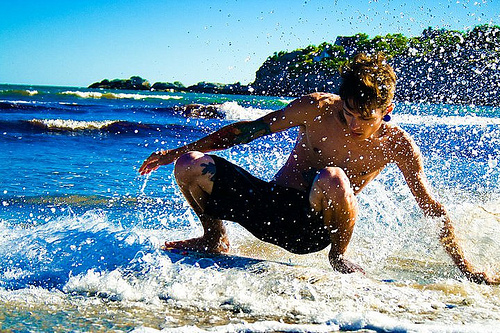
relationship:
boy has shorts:
[132, 56, 498, 291] [203, 147, 335, 262]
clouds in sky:
[233, 59, 264, 69] [2, 2, 496, 84]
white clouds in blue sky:
[204, 28, 261, 70] [0, 0, 497, 84]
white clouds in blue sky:
[166, 57, 255, 80] [0, 0, 497, 84]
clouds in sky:
[39, 25, 260, 85] [2, 2, 496, 84]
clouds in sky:
[164, 31, 211, 63] [19, 5, 250, 74]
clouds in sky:
[109, 27, 249, 82] [17, 3, 495, 110]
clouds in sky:
[72, 0, 256, 55] [74, 21, 246, 65]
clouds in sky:
[203, 39, 249, 52] [122, 20, 217, 75]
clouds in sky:
[160, 12, 260, 72] [79, 30, 107, 48]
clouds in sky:
[37, 32, 77, 58] [17, 3, 495, 110]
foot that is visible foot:
[328, 248, 365, 288] [328, 248, 365, 288]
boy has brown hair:
[132, 56, 498, 291] [336, 48, 403, 110]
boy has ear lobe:
[132, 56, 498, 291] [384, 112, 391, 122]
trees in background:
[412, 33, 472, 109] [11, 16, 484, 96]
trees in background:
[257, 45, 443, 96] [11, 16, 484, 96]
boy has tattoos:
[132, 56, 498, 291] [162, 113, 272, 153]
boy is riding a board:
[132, 56, 498, 291] [133, 221, 478, 316]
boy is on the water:
[132, 56, 498, 291] [2, 99, 488, 324]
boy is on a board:
[132, 56, 498, 291] [135, 235, 498, 304]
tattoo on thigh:
[197, 157, 223, 186] [184, 149, 267, 201]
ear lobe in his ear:
[384, 112, 391, 122] [381, 105, 395, 122]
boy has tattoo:
[132, 56, 498, 291] [195, 112, 287, 147]